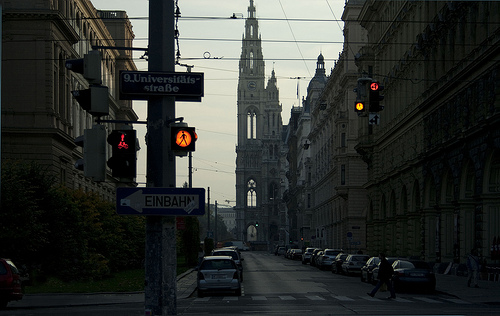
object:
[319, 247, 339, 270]
car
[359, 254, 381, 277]
car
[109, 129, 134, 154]
sign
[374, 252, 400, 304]
pedestrian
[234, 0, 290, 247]
building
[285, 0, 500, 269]
building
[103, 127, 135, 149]
light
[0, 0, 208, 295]
building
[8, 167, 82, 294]
trees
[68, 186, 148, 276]
bushes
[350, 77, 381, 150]
light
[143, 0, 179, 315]
pole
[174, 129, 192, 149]
crosswalk light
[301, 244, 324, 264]
cars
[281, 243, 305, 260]
cars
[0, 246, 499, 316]
street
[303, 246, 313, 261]
vehicle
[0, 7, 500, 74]
cables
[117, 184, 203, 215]
signs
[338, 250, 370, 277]
car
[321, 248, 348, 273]
car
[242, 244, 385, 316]
road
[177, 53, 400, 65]
wires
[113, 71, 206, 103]
sign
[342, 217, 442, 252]
bad sentence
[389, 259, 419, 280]
car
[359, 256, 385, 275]
car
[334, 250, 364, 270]
car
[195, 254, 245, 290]
car